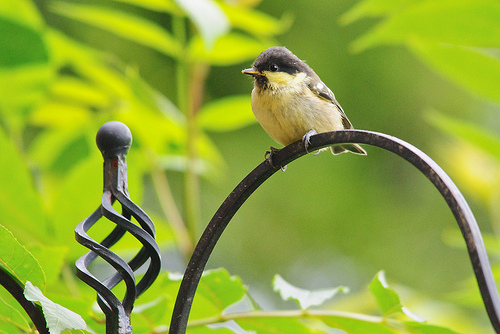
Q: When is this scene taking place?
A: Day time.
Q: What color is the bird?
A: Yellow and black.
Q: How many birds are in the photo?
A: One.